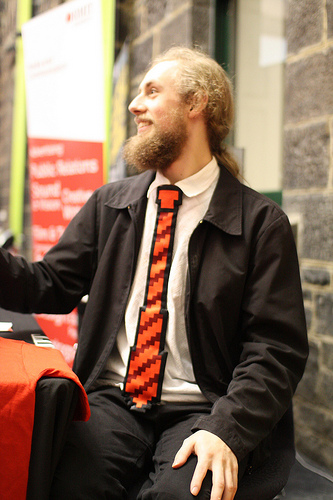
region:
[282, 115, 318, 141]
White grout line on brick wall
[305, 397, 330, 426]
White grout line on brick wall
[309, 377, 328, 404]
White grout line on brick wall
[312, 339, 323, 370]
White grout line on brick wall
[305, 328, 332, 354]
White grout line on brick wall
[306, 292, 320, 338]
White grout line on brick wall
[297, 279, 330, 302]
White grout line on brick wall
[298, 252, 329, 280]
White grout line on brick wall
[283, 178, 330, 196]
White grout line on brick wall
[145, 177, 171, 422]
Orange and red tie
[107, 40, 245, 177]
head of the man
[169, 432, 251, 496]
hand of the man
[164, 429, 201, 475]
thumb of the man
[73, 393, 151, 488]
black pants on the man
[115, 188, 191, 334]
orange tie on the man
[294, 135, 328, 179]
gray wall behind the man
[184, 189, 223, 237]
white shirt on the man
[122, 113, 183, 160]
beard on the man's face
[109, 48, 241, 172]
man smiling in the photo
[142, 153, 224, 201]
collar of the shirt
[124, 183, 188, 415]
a long red and black tie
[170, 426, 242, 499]
the hand of a man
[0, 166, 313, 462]
a man's black jacket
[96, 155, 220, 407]
part of a man's white collared shirt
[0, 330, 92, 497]
part of a short sleeve shirt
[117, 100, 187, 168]
a man's brown beard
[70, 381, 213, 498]
a man's black pants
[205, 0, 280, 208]
part of a building's window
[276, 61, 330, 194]
gray brick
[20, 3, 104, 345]
a tall red and white sign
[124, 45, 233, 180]
Man with long hair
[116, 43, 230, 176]
Man with full beard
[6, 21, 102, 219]
White and orange sign on green posts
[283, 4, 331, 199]
Wall with large gray stone bricks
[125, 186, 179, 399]
Orange and black pixel design tie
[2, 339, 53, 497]
Orange tshirt laying on table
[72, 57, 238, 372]
Man wearing black jacket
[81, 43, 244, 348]
Man wearing white shirt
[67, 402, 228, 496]
Man wearing black pants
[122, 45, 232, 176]
Man with trimmed mustache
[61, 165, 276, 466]
the jacket is black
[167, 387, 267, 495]
man's hand on his lap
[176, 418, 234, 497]
man's hand on his lap